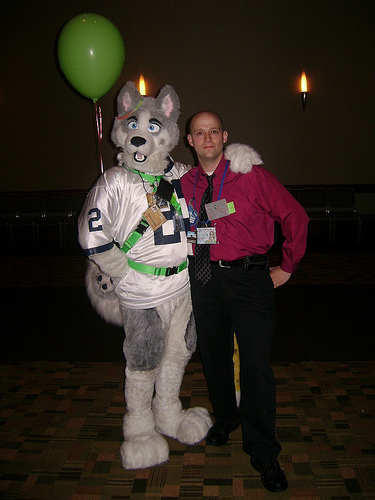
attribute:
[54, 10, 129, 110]
balloon — green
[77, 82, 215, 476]
person — spotted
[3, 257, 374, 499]
floor — checkered